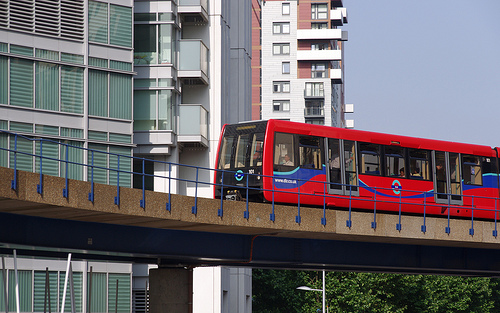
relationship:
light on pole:
[294, 284, 324, 294] [321, 268, 327, 313]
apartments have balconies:
[134, 0, 220, 202] [177, 38, 212, 86]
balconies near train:
[177, 38, 212, 86] [211, 120, 498, 225]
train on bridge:
[211, 120, 498, 225] [0, 125, 500, 280]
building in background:
[1, 1, 134, 188] [0, 1, 499, 199]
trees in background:
[252, 268, 499, 313] [0, 1, 499, 199]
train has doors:
[211, 120, 498, 225] [324, 136, 360, 197]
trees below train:
[252, 268, 499, 313] [211, 120, 498, 225]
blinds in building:
[62, 3, 88, 44] [1, 1, 134, 188]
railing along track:
[1, 130, 499, 238] [3, 162, 500, 250]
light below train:
[294, 284, 324, 294] [211, 120, 498, 225]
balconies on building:
[177, 38, 212, 86] [1, 1, 134, 188]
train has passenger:
[211, 120, 498, 225] [396, 165, 407, 176]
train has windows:
[211, 120, 498, 225] [274, 133, 299, 166]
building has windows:
[1, 1, 134, 188] [88, 68, 136, 127]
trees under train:
[252, 268, 499, 313] [211, 120, 498, 225]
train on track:
[211, 120, 498, 225] [3, 162, 500, 250]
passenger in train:
[396, 165, 407, 176] [211, 120, 498, 225]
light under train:
[294, 284, 324, 294] [211, 120, 498, 225]